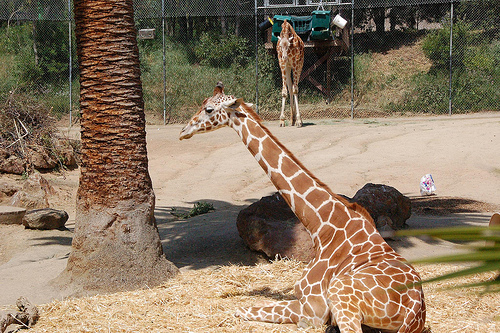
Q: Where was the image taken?
A: It was taken at the zoo.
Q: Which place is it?
A: It is a zoo.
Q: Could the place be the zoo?
A: Yes, it is the zoo.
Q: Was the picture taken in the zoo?
A: Yes, it was taken in the zoo.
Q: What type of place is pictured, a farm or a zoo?
A: It is a zoo.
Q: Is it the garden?
A: No, it is the zoo.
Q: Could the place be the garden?
A: No, it is the zoo.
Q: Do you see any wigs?
A: No, there are no wigs.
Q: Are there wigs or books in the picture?
A: No, there are no wigs or books.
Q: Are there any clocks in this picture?
A: No, there are no clocks.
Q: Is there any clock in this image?
A: No, there are no clocks.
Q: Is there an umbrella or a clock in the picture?
A: No, there are no clocks or umbrellas.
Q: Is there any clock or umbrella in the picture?
A: No, there are no clocks or umbrellas.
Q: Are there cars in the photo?
A: No, there are no cars.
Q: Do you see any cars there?
A: No, there are no cars.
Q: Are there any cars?
A: No, there are no cars.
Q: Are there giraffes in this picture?
A: Yes, there is a giraffe.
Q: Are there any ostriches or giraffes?
A: Yes, there is a giraffe.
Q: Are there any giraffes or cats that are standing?
A: Yes, the giraffe is standing.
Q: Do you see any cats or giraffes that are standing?
A: Yes, the giraffe is standing.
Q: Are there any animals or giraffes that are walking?
A: Yes, the giraffe is walking.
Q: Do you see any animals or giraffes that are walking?
A: Yes, the giraffe is walking.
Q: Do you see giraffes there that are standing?
A: Yes, there is a giraffe that is standing.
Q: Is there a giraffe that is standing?
A: Yes, there is a giraffe that is standing.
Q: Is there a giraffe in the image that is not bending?
A: Yes, there is a giraffe that is standing.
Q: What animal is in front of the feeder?
A: The giraffe is in front of the feeder.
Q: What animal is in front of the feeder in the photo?
A: The animal is a giraffe.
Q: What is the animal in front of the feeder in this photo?
A: The animal is a giraffe.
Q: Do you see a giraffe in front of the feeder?
A: Yes, there is a giraffe in front of the feeder.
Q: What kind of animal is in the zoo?
A: The animal is a giraffe.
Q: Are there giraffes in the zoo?
A: Yes, there is a giraffe in the zoo.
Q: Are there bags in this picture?
A: Yes, there is a bag.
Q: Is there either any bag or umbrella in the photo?
A: Yes, there is a bag.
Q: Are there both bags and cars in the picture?
A: No, there is a bag but no cars.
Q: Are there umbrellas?
A: No, there are no umbrellas.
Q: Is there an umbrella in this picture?
A: No, there are no umbrellas.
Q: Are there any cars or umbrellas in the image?
A: No, there are no umbrellas or cars.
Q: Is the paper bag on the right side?
A: Yes, the bag is on the right of the image.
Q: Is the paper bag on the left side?
A: No, the bag is on the right of the image.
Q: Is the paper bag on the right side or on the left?
A: The bag is on the right of the image.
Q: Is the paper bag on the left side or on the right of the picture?
A: The bag is on the right of the image.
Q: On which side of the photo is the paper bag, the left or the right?
A: The bag is on the right of the image.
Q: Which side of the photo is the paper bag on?
A: The bag is on the right of the image.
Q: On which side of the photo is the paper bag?
A: The bag is on the right of the image.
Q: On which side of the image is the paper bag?
A: The bag is on the right of the image.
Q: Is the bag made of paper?
A: Yes, the bag is made of paper.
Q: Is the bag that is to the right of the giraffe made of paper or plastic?
A: The bag is made of paper.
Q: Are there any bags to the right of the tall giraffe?
A: Yes, there is a bag to the right of the giraffe.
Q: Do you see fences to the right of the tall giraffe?
A: No, there is a bag to the right of the giraffe.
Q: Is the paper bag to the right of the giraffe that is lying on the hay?
A: Yes, the bag is to the right of the giraffe.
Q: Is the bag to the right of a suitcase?
A: No, the bag is to the right of the giraffe.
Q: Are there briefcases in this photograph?
A: No, there are no briefcases.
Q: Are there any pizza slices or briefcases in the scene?
A: No, there are no briefcases or pizza slices.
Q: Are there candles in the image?
A: No, there are no candles.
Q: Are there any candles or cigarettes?
A: No, there are no candles or cigarettes.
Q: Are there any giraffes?
A: Yes, there is a giraffe.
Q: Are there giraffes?
A: Yes, there is a giraffe.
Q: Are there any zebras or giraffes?
A: Yes, there is a giraffe.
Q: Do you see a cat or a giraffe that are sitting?
A: Yes, the giraffe is sitting.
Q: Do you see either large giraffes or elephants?
A: Yes, there is a large giraffe.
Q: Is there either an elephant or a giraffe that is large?
A: Yes, the giraffe is large.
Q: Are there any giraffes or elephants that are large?
A: Yes, the giraffe is large.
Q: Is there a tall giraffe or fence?
A: Yes, there is a tall giraffe.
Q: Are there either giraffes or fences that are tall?
A: Yes, the giraffe is tall.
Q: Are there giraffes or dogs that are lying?
A: Yes, the giraffe is lying.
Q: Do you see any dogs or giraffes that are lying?
A: Yes, the giraffe is lying.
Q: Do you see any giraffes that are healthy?
A: Yes, there is a healthy giraffe.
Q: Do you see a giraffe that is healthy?
A: Yes, there is a giraffe that is healthy.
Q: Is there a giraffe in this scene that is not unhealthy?
A: Yes, there is an healthy giraffe.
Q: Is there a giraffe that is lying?
A: Yes, there is a giraffe that is lying.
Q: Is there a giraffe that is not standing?
A: Yes, there is a giraffe that is lying.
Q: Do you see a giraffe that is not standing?
A: Yes, there is a giraffe that is lying .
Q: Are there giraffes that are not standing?
A: Yes, there is a giraffe that is lying.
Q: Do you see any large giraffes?
A: Yes, there is a large giraffe.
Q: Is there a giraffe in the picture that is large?
A: Yes, there is a giraffe that is large.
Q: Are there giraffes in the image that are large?
A: Yes, there is a giraffe that is large.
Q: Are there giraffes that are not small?
A: Yes, there is a large giraffe.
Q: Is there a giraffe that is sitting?
A: Yes, there is a giraffe that is sitting.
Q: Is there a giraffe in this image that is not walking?
A: Yes, there is a giraffe that is sitting.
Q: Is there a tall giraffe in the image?
A: Yes, there is a tall giraffe.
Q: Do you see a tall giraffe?
A: Yes, there is a tall giraffe.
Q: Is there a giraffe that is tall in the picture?
A: Yes, there is a tall giraffe.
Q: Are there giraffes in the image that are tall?
A: Yes, there is a giraffe that is tall.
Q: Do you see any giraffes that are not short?
A: Yes, there is a tall giraffe.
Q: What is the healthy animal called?
A: The animal is a giraffe.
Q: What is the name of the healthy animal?
A: The animal is a giraffe.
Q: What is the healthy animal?
A: The animal is a giraffe.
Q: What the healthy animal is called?
A: The animal is a giraffe.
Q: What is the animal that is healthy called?
A: The animal is a giraffe.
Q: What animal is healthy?
A: The animal is a giraffe.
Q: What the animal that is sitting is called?
A: The animal is a giraffe.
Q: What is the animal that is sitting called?
A: The animal is a giraffe.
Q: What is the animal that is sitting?
A: The animal is a giraffe.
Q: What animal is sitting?
A: The animal is a giraffe.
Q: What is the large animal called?
A: The animal is a giraffe.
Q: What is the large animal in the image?
A: The animal is a giraffe.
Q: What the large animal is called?
A: The animal is a giraffe.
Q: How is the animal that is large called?
A: The animal is a giraffe.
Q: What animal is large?
A: The animal is a giraffe.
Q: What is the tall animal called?
A: The animal is a giraffe.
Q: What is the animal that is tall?
A: The animal is a giraffe.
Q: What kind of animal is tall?
A: The animal is a giraffe.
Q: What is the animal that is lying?
A: The animal is a giraffe.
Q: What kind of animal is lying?
A: The animal is a giraffe.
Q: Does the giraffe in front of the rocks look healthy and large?
A: Yes, the giraffe is healthy and large.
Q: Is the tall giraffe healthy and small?
A: No, the giraffe is healthy but large.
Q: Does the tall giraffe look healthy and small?
A: No, the giraffe is healthy but large.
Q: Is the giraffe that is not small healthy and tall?
A: Yes, the giraffe is healthy and tall.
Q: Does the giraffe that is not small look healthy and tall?
A: Yes, the giraffe is healthy and tall.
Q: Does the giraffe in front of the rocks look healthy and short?
A: No, the giraffe is healthy but tall.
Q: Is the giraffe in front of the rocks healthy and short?
A: No, the giraffe is healthy but tall.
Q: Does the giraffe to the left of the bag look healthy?
A: Yes, the giraffe is healthy.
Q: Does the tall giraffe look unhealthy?
A: No, the giraffe is healthy.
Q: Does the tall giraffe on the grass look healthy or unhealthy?
A: The giraffe is healthy.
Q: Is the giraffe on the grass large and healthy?
A: Yes, the giraffe is large and healthy.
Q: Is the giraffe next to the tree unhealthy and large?
A: No, the giraffe is large but healthy.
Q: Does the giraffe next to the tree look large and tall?
A: Yes, the giraffe is large and tall.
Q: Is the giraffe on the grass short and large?
A: No, the giraffe is large but tall.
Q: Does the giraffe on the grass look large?
A: Yes, the giraffe is large.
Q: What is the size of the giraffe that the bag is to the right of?
A: The giraffe is large.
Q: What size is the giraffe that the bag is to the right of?
A: The giraffe is large.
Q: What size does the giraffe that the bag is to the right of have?
A: The giraffe has large size.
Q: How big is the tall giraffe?
A: The giraffe is large.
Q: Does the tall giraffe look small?
A: No, the giraffe is large.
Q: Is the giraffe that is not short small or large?
A: The giraffe is large.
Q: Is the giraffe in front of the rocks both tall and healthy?
A: Yes, the giraffe is tall and healthy.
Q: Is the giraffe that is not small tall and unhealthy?
A: No, the giraffe is tall but healthy.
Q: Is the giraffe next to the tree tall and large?
A: Yes, the giraffe is tall and large.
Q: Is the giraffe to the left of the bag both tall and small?
A: No, the giraffe is tall but large.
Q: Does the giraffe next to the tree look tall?
A: Yes, the giraffe is tall.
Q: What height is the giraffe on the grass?
A: The giraffe is tall.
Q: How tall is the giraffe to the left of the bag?
A: The giraffe is tall.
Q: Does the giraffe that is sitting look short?
A: No, the giraffe is tall.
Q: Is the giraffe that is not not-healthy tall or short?
A: The giraffe is tall.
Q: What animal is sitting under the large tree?
A: The giraffe is sitting under the tree.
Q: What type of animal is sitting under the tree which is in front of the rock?
A: The animal is a giraffe.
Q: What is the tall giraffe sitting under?
A: The giraffe is sitting under the tree.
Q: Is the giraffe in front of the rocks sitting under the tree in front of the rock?
A: Yes, the giraffe is sitting under the tree.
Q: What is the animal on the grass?
A: The animal is a giraffe.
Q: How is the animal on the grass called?
A: The animal is a giraffe.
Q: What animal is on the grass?
A: The animal is a giraffe.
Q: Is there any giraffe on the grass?
A: Yes, there is a giraffe on the grass.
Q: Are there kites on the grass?
A: No, there is a giraffe on the grass.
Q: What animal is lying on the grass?
A: The giraffe is lying on the grass.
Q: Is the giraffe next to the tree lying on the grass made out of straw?
A: Yes, the giraffe is lying on the grass.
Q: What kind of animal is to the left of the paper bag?
A: The animal is a giraffe.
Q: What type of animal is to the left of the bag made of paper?
A: The animal is a giraffe.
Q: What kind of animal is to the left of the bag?
A: The animal is a giraffe.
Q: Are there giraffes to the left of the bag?
A: Yes, there is a giraffe to the left of the bag.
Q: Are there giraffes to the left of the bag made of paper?
A: Yes, there is a giraffe to the left of the bag.